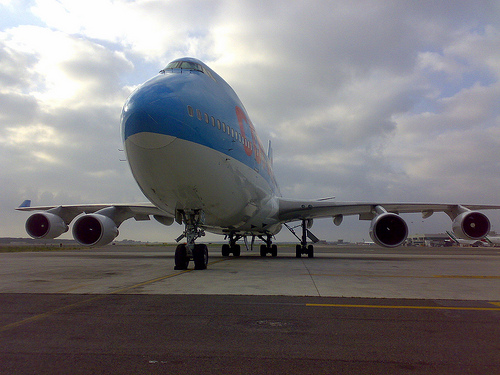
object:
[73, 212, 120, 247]
jet engine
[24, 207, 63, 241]
jet engine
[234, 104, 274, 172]
writing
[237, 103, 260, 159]
letters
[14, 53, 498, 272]
aircraft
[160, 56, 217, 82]
cockpit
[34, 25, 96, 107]
sunlight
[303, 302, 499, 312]
stripe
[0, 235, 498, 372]
runway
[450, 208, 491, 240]
airplane engine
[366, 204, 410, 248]
airplane engine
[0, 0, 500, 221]
sky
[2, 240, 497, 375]
airfield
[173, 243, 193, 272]
gear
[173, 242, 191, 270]
wheels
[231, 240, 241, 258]
wheels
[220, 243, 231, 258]
wheels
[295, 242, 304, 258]
wheels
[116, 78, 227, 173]
nose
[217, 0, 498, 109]
clouds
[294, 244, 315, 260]
landing gear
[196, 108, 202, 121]
window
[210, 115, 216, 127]
window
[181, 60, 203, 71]
window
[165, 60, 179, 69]
window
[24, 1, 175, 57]
cloud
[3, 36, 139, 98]
cloud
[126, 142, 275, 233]
underbelly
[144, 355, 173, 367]
pool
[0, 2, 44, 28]
patch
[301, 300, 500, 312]
line